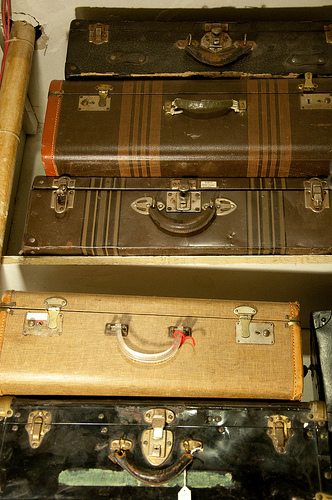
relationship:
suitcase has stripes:
[26, 173, 331, 261] [78, 180, 285, 253]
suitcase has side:
[38, 76, 331, 173] [41, 74, 68, 174]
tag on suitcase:
[173, 466, 194, 500] [1, 393, 331, 500]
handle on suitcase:
[117, 320, 186, 371] [2, 288, 307, 403]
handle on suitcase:
[143, 197, 214, 237] [26, 173, 331, 261]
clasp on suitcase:
[22, 408, 54, 450] [1, 393, 331, 500]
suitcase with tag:
[1, 393, 331, 500] [173, 466, 194, 500]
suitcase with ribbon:
[2, 288, 307, 403] [175, 325, 196, 350]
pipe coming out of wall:
[4, 19, 29, 253] [8, 4, 85, 137]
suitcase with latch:
[1, 393, 331, 500] [139, 411, 173, 469]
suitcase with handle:
[2, 288, 307, 403] [117, 320, 186, 371]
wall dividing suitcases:
[1, 250, 329, 288] [1, 2, 330, 500]